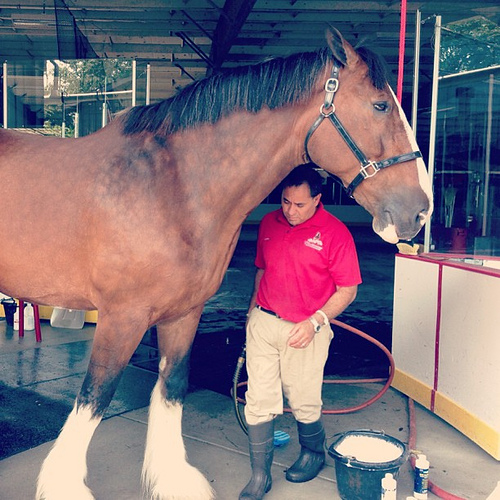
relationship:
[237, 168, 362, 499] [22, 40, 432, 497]
man appears to be bathing horse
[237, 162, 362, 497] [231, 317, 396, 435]
man holding hose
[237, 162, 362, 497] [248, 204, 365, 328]
man wearing a shirt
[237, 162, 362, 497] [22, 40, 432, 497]
man getting ready to wash horse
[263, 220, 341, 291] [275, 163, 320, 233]
shirt on man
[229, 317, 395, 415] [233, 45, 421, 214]
hose washes horse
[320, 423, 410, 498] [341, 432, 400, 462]
bucket has soapy water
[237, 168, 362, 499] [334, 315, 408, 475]
man carries hose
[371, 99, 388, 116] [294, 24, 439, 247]
eye on head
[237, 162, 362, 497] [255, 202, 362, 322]
man wears shirt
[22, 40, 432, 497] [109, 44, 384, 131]
horse has mane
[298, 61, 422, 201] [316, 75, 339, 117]
harness has buckle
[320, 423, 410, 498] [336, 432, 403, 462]
bucket has soapy water